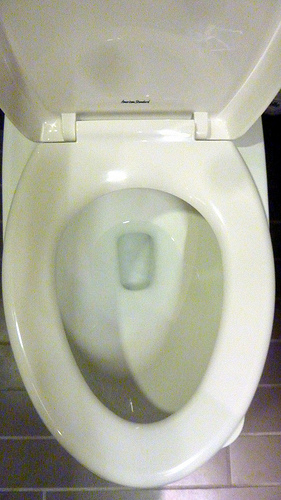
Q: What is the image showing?
A: It is showing a bathroom.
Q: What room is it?
A: It is a bathroom.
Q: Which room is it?
A: It is a bathroom.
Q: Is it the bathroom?
A: Yes, it is the bathroom.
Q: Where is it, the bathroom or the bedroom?
A: It is the bathroom.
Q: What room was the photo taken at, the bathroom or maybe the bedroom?
A: It was taken at the bathroom.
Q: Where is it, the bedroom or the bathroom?
A: It is the bathroom.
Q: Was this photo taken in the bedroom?
A: No, the picture was taken in the bathroom.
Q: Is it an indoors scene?
A: Yes, it is indoors.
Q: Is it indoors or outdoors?
A: It is indoors.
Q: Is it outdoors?
A: No, it is indoors.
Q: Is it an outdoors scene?
A: No, it is indoors.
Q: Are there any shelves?
A: No, there are no shelves.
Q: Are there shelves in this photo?
A: No, there are no shelves.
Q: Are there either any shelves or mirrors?
A: No, there are no shelves or mirrors.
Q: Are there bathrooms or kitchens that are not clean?
A: No, there is a bathroom but it is clean.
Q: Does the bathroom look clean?
A: Yes, the bathroom is clean.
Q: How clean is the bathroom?
A: The bathroom is clean.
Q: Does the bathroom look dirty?
A: No, the bathroom is clean.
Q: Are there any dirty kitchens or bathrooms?
A: No, there is a bathroom but it is clean.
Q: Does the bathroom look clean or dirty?
A: The bathroom is clean.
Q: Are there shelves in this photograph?
A: No, there are no shelves.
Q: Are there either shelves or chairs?
A: No, there are no shelves or chairs.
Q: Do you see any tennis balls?
A: No, there are no tennis balls.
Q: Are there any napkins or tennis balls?
A: No, there are no tennis balls or napkins.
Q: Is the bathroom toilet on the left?
A: Yes, the toilet is on the left of the image.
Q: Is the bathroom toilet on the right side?
A: No, the toilet is on the left of the image.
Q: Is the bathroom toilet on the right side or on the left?
A: The toilet is on the left of the image.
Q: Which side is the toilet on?
A: The toilet is on the left of the image.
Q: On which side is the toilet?
A: The toilet is on the left of the image.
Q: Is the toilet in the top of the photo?
A: Yes, the toilet is in the top of the image.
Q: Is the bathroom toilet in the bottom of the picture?
A: No, the toilet is in the top of the image.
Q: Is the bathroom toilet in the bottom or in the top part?
A: The toilet is in the top of the image.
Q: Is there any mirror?
A: No, there are no mirrors.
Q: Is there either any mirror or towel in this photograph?
A: No, there are no mirrors or towels.